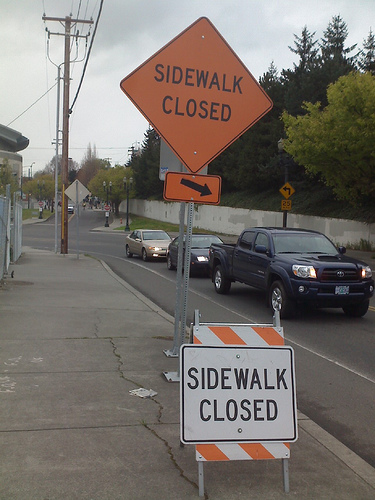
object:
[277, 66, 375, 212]
tree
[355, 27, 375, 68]
tree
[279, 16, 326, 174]
tree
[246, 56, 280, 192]
tree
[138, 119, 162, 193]
tree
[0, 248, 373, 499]
sidewalk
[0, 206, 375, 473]
road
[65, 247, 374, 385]
line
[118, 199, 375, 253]
wall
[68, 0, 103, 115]
cord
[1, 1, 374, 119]
air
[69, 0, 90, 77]
cord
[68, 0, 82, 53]
cord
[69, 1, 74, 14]
cord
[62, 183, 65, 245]
board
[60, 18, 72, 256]
pole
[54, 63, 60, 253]
pole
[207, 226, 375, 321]
car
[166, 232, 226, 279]
car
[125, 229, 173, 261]
car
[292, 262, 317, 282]
lights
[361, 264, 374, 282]
lights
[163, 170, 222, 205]
sign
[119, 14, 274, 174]
sign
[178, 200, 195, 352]
pole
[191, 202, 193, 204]
holes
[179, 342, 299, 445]
sign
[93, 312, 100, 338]
cracks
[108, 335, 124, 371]
cracks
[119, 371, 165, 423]
cracks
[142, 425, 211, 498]
cracks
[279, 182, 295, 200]
sign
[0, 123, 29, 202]
house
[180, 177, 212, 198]
arrow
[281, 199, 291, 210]
sign